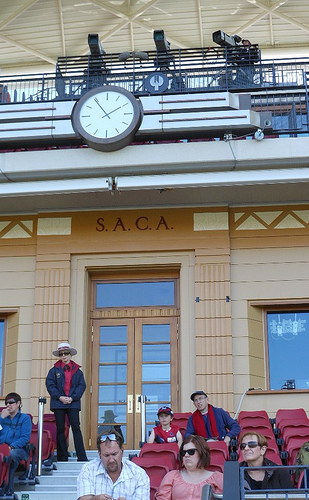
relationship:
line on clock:
[105, 128, 108, 139] [85, 78, 142, 145]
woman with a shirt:
[152, 433, 225, 498] [156, 467, 226, 499]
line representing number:
[105, 128, 108, 139] [79, 112, 92, 118]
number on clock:
[79, 112, 92, 118] [69, 85, 141, 151]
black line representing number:
[105, 89, 109, 102] [114, 93, 122, 102]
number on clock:
[114, 93, 122, 102] [72, 84, 141, 144]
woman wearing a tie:
[45, 343, 89, 461] [62, 364, 70, 371]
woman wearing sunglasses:
[45, 343, 89, 461] [58, 351, 69, 354]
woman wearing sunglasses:
[45, 343, 89, 461] [59, 349, 69, 356]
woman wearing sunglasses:
[152, 433, 225, 498] [178, 448, 196, 455]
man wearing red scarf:
[30, 335, 110, 462] [191, 402, 220, 443]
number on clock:
[114, 93, 122, 101] [69, 85, 141, 151]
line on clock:
[90, 96, 122, 121] [85, 71, 162, 153]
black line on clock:
[102, 89, 110, 102] [74, 91, 144, 149]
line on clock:
[105, 128, 108, 139] [69, 85, 141, 151]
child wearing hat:
[134, 401, 200, 450] [149, 391, 200, 421]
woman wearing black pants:
[45, 343, 89, 461] [52, 409, 88, 461]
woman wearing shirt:
[45, 343, 89, 461] [59, 358, 73, 387]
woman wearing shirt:
[152, 433, 225, 498] [154, 469, 222, 499]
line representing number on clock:
[84, 103, 92, 109] [69, 85, 141, 151]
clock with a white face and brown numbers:
[70, 79, 153, 167] [117, 99, 134, 126]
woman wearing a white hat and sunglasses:
[153, 429, 226, 498] [55, 349, 74, 391]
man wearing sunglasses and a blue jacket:
[78, 418, 154, 500] [0, 411, 31, 447]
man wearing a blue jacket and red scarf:
[191, 390, 224, 441] [185, 407, 218, 437]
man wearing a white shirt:
[78, 460, 148, 498] [73, 455, 150, 499]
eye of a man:
[106, 453, 117, 477] [78, 418, 154, 500]